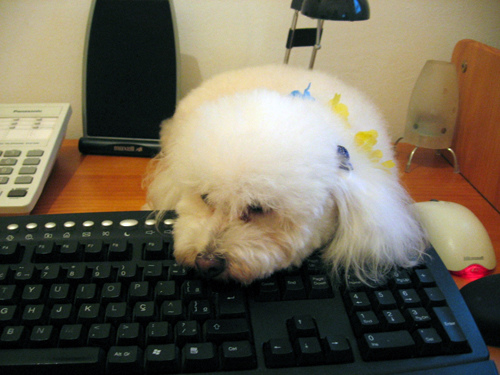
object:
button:
[6, 223, 18, 230]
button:
[26, 222, 39, 229]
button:
[45, 221, 55, 229]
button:
[62, 220, 75, 227]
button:
[82, 220, 94, 227]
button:
[100, 219, 113, 227]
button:
[119, 218, 139, 227]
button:
[144, 219, 157, 226]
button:
[164, 218, 174, 225]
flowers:
[279, 81, 397, 178]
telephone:
[0, 101, 74, 216]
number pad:
[339, 247, 435, 288]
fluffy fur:
[342, 212, 421, 261]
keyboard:
[0, 208, 499, 375]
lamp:
[283, 1, 371, 88]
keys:
[34, 259, 250, 343]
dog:
[141, 61, 427, 286]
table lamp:
[392, 59, 458, 174]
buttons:
[60, 273, 201, 340]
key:
[129, 281, 148, 297]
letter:
[134, 283, 140, 289]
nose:
[192, 250, 226, 277]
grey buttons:
[0, 148, 45, 183]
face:
[173, 158, 300, 282]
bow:
[336, 145, 354, 173]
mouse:
[407, 199, 497, 276]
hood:
[290, 0, 373, 23]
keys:
[263, 314, 352, 367]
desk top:
[5, 114, 425, 211]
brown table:
[34, 136, 499, 373]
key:
[201, 318, 251, 340]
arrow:
[297, 319, 302, 324]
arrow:
[331, 342, 339, 345]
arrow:
[304, 343, 309, 349]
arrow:
[273, 345, 281, 349]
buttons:
[350, 286, 467, 353]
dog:
[145, 99, 402, 260]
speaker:
[79, 0, 178, 160]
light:
[465, 263, 485, 277]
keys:
[346, 287, 467, 360]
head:
[145, 89, 422, 282]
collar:
[320, 144, 354, 173]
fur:
[140, 60, 424, 287]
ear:
[318, 166, 426, 285]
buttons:
[2, 240, 166, 260]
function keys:
[6, 218, 173, 232]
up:
[288, 316, 318, 336]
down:
[295, 331, 319, 353]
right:
[326, 335, 349, 353]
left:
[263, 338, 292, 363]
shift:
[203, 319, 252, 340]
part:
[86, 175, 117, 195]